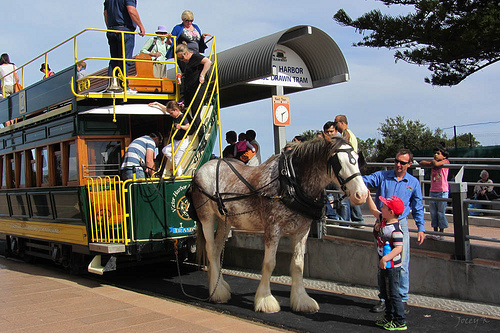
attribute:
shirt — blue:
[366, 170, 426, 230]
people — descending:
[167, 12, 212, 146]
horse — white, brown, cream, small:
[194, 140, 367, 314]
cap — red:
[380, 195, 405, 215]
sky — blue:
[2, 0, 500, 162]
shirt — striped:
[376, 222, 402, 265]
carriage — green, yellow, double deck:
[0, 28, 223, 281]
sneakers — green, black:
[383, 320, 405, 329]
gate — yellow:
[85, 173, 128, 242]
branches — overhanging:
[331, 0, 499, 84]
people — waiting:
[225, 128, 265, 164]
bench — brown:
[70, 57, 171, 86]